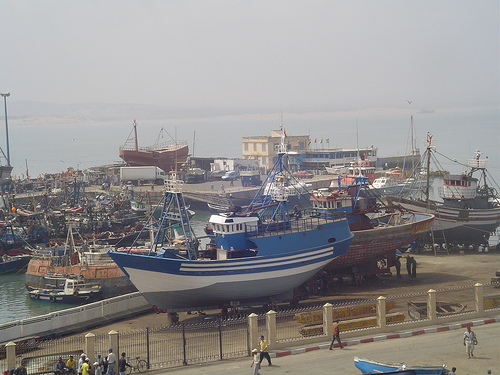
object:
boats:
[268, 181, 439, 290]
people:
[393, 251, 403, 280]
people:
[403, 252, 414, 275]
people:
[409, 257, 419, 284]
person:
[252, 346, 259, 373]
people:
[8, 347, 130, 372]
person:
[329, 320, 347, 353]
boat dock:
[16, 136, 498, 356]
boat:
[397, 156, 498, 226]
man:
[108, 206, 355, 321]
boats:
[105, 171, 349, 303]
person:
[254, 333, 271, 363]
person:
[462, 322, 479, 359]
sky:
[3, 5, 498, 84]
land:
[2, 92, 497, 124]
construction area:
[0, 59, 499, 341]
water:
[0, 115, 500, 172]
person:
[113, 352, 132, 374]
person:
[103, 345, 118, 374]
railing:
[107, 313, 248, 372]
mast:
[0, 91, 12, 178]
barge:
[1, 190, 197, 274]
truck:
[119, 164, 171, 187]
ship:
[119, 118, 193, 173]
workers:
[395, 251, 418, 276]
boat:
[340, 209, 447, 270]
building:
[183, 133, 382, 193]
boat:
[29, 279, 101, 300]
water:
[0, 252, 100, 328]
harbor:
[5, 124, 497, 375]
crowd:
[0, 332, 139, 374]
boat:
[101, 195, 304, 278]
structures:
[199, 153, 330, 241]